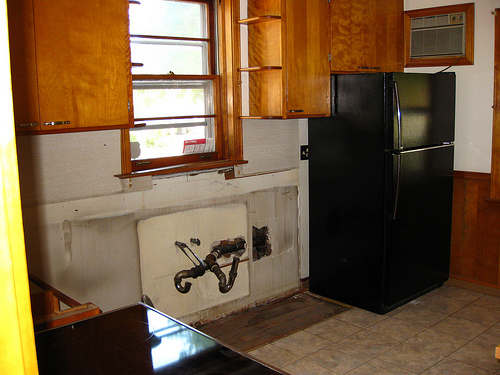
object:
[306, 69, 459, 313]
refrigerator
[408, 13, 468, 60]
a.c. unit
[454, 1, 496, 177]
wall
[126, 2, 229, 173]
window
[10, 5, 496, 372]
kitchen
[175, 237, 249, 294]
pipes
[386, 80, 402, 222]
handles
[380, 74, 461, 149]
freezer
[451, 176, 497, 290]
wood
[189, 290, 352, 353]
patch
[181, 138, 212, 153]
sign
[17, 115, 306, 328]
wall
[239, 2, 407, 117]
cabinets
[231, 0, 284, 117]
shelves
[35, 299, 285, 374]
counter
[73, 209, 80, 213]
black spot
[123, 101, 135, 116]
bracket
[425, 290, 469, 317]
tile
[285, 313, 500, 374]
floor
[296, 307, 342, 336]
tile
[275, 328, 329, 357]
tile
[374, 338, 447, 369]
tile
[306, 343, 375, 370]
tile